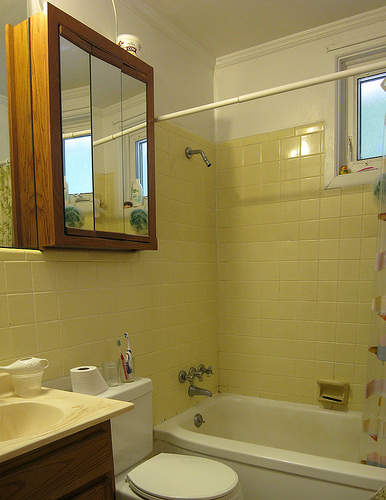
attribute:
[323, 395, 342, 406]
item — black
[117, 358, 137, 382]
glass — clear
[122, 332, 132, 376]
toothbrush — blue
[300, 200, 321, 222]
tile — moldy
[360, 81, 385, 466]
shower curtain — clear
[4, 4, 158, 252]
frame — brown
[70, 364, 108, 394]
toilet paper — white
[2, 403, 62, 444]
sink — bathroom, tan colored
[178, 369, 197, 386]
faucet — silver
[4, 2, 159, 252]
medicine cabinet — wooden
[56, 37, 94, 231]
mirror — 3-panel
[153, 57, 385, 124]
rod — white, extendable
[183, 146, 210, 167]
shower head — silver, small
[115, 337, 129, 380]
toothbrush — orange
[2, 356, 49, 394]
teapot — little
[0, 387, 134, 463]
counter — beige, ivory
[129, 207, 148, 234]
shower poof — blue, green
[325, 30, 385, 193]
rim — white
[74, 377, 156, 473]
cistern — toilet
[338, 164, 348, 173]
ducky — yellow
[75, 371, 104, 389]
tissue — roll